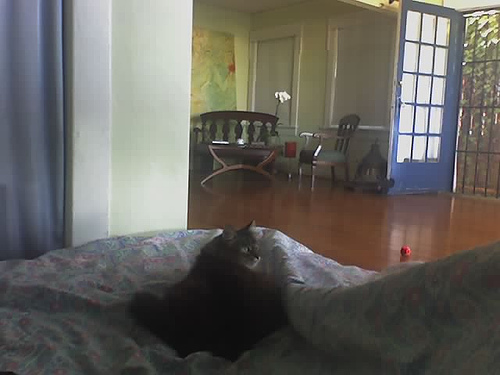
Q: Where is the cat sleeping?
A: On the bed.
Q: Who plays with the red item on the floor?
A: Cat.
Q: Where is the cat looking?
A: To the right.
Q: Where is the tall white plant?
A: On the table.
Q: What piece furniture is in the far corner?
A: Loveseat.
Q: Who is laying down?
A: Cat.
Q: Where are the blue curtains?
A: Beside the blanket.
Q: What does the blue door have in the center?
A: Glass panes.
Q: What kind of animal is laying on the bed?
A: A cat.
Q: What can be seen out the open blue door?
A: Green trees.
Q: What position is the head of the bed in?
A: Elevated.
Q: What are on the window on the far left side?
A: Blue curtains.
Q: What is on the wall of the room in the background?
A: Wallpaper.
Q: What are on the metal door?
A: Metal crossbars.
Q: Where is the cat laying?
A: Foot of bed.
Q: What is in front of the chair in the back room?
A: Low table.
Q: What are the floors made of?
A: Wood.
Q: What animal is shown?
A: A cat.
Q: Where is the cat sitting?
A: On a bed.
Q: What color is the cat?
A: Grey.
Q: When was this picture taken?
A: Daytime.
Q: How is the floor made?
A: Of wood.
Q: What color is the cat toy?
A: Red.